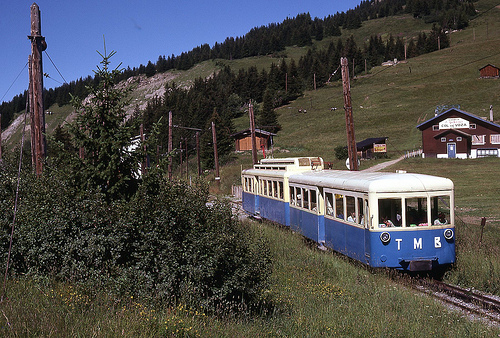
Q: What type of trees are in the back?
A: Pine trees.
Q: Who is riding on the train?
A: Passengers.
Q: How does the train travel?
A: On the tracks.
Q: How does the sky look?
A: Clear.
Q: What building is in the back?
A: Barn.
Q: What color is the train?
A: White and blue.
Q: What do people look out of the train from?
A: Windows.